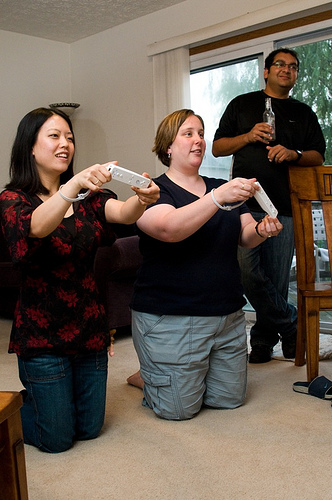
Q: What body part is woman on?
A: Knees.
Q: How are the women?
A: On their knees.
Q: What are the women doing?
A: Kneeling.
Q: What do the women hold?
A: Wii remote controls.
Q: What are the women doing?
A: They are kneeling.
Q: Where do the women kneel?
A: On the carpet.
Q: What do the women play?
A: A Wii video game.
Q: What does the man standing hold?
A: A glass bottle.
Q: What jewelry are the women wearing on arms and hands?
A: Rings and wrist watch.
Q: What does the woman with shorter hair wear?
A: A black shirt and gray cargo pants.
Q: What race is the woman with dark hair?
A: She is Asian.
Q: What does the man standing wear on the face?
A: He wears eye glasses.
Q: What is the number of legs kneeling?
A: There are four.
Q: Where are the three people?
A: A room.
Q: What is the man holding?
A: A bottle.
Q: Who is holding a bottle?
A: The man.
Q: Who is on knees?
A: Two women.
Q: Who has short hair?
A: Woman near man.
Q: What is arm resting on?
A: Chair.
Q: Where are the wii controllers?
A: In hands.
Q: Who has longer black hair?
A: Lady in jeans.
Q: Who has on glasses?
A: Person standing.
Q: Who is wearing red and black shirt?
A: Asian lady.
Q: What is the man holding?
A: A bottle.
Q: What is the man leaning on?
A: A chair.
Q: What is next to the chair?
A: A sandal.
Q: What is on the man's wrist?
A: A watch.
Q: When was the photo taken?
A: Daytime.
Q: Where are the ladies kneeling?
A: On the carpet.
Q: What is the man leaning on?
A: The back of a chair.